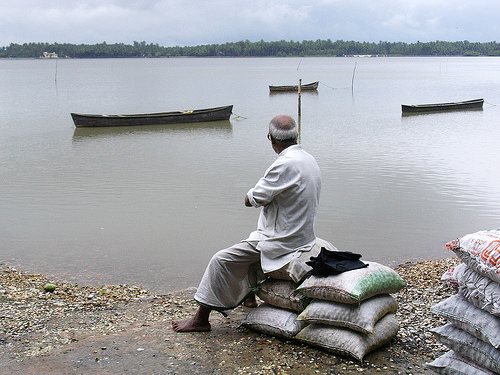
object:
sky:
[1, 0, 500, 40]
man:
[171, 116, 321, 333]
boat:
[71, 105, 233, 127]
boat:
[269, 82, 319, 91]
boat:
[401, 98, 483, 115]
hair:
[268, 122, 296, 139]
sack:
[294, 259, 406, 303]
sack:
[296, 292, 398, 334]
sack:
[295, 315, 400, 358]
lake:
[1, 57, 500, 267]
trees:
[133, 41, 142, 56]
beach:
[1, 257, 468, 374]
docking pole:
[298, 79, 301, 115]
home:
[40, 52, 57, 58]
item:
[305, 247, 369, 277]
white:
[247, 143, 321, 274]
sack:
[241, 303, 309, 338]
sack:
[256, 278, 313, 312]